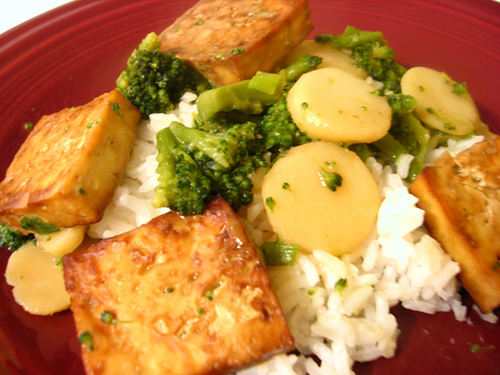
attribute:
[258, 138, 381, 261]
potato — golden, yellow, scalloped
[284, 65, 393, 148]
potato — golden, yellow, scalloped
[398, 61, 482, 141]
potato — golden, yellow, scalloped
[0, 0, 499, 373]
food — varied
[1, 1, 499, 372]
plate — red, round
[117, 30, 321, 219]
broccoli — soft cooked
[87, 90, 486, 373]
rice — white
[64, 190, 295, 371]
food — square, cooked, browned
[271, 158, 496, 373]
rice — white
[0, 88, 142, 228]
tofu — sliced, cooked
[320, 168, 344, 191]
broccoli — small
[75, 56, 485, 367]
rice — white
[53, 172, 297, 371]
tofu — square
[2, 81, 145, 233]
tofu — square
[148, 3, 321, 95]
tofu — square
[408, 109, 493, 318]
tofu — square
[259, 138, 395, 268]
water chestnut — round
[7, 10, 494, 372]
dish — vegetarian